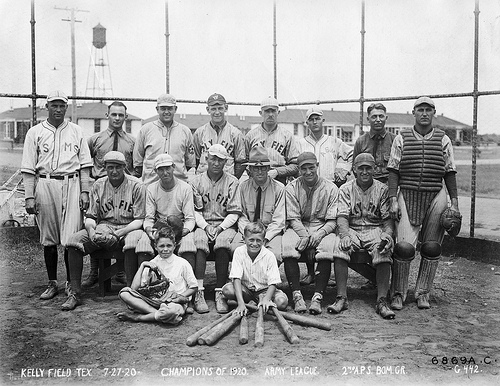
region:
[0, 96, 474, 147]
buildings in background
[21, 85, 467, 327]
baseball players posing in vintage photo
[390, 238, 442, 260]
player wearing knee pads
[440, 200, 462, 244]
baseball glove in player's hand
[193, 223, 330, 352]
boy with his hands on baseball bats spread on ground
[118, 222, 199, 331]
boy sitting cross-legged on ground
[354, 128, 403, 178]
man wearing dark shirt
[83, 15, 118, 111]
large water tower in distance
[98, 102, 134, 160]
man wearing dark tie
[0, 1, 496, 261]
tall fence behind posing group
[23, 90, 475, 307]
a baseball team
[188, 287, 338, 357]
seven wood baseball bats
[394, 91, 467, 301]
the catcher of the team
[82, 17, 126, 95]
a tall water tower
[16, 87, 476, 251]
a old baseball team picture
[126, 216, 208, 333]
a young boy sitting on the ground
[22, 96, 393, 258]
a group of men wearing the same outfit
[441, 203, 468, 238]
a baseball glove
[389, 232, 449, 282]
two knee pads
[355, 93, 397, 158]
man in button up shirt and tie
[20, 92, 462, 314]
baseball team posing together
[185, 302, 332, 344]
baseball bats on ground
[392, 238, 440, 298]
knee pads and shin guards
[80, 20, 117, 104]
water tower behind baseball team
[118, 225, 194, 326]
boy with catchers glove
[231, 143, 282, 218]
man wearing dress shirt, tie, and hat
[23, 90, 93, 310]
man wearing baseball uniform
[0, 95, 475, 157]
buildings behind baseball players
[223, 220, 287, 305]
boy crouching on the ground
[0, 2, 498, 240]
fence behind baseball team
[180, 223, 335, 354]
Boy with baseball bats.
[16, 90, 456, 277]
Posing baseball team.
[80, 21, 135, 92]
Water Tower in background.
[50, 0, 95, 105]
Power Pole in background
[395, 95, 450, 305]
Standing Umpire with glove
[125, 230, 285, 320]
Two sitting smiling Boys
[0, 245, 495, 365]
Flat Dirt and Sandy Floor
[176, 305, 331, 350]
Baseball Bats on Ground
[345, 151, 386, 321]
Smiling baseball player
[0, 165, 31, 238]
Gas powered Push Lawnmower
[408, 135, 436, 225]
protection worn by the catcher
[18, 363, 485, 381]
white lettering at the bottom of the photo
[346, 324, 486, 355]
dirt in front of the players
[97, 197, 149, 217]
dark lettering on players jersey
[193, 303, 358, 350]
seven baseball bats on the ground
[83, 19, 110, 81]
water tower in the backdrop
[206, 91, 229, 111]
dark colored hat on a player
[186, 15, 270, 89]
bright sky in the backdrop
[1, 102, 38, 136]
housing in the backdrop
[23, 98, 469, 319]
a team of baseball players